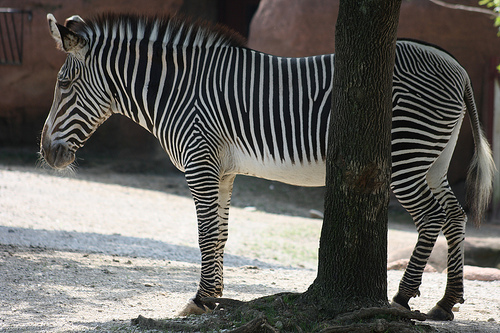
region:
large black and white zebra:
[36, 10, 491, 317]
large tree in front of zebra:
[301, 2, 413, 317]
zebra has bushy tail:
[457, 68, 498, 219]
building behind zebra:
[2, 4, 188, 150]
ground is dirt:
[2, 150, 497, 331]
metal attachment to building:
[0, 4, 26, 66]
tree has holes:
[342, 152, 384, 212]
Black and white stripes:
[186, 64, 303, 146]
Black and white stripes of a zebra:
[37, 52, 304, 184]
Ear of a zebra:
[34, 8, 84, 66]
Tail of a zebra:
[450, 64, 499, 224]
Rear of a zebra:
[408, 23, 493, 228]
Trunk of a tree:
[316, 11, 403, 241]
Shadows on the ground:
[16, 206, 150, 316]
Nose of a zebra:
[34, 133, 56, 165]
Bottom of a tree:
[281, 244, 382, 320]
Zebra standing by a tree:
[45, 11, 496, 326]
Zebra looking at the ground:
[30, 7, 495, 327]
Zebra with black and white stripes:
[35, 10, 492, 325]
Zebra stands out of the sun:
[35, 7, 491, 322]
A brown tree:
[316, 3, 396, 318]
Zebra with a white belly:
[35, 12, 495, 324]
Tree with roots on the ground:
[202, 20, 442, 331]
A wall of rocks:
[4, 3, 499, 191]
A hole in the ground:
[382, 226, 498, 292]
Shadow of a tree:
[0, 220, 287, 318]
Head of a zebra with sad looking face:
[35, 13, 137, 170]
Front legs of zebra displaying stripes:
[176, 134, 243, 314]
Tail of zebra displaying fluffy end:
[458, 71, 498, 220]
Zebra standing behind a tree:
[31, 15, 498, 316]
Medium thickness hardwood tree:
[318, 7, 395, 303]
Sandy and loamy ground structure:
[6, 183, 151, 320]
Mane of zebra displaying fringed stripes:
[88, 16, 243, 44]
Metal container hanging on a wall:
[0, 10, 33, 66]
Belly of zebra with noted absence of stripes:
[209, 123, 332, 185]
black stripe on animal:
[260, 52, 274, 182]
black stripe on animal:
[128, 35, 152, 115]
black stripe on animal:
[98, 38, 123, 89]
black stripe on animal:
[181, 151, 222, 175]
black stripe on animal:
[378, 103, 436, 135]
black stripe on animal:
[417, 75, 457, 115]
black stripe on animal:
[402, 185, 432, 209]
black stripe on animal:
[185, 169, 217, 191]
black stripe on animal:
[310, 56, 325, 161]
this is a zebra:
[25, 11, 488, 330]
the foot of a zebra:
[434, 185, 485, 317]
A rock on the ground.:
[96, 262, 111, 273]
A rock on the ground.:
[124, 276, 136, 288]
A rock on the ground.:
[133, 292, 145, 307]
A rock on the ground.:
[93, 305, 100, 316]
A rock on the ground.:
[121, 257, 128, 267]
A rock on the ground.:
[110, 257, 119, 266]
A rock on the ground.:
[241, 265, 267, 270]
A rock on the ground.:
[271, 279, 278, 286]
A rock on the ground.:
[267, 264, 272, 272]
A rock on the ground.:
[291, 287, 305, 296]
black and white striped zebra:
[22, 9, 480, 314]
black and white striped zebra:
[24, 8, 478, 309]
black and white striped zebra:
[30, 12, 481, 325]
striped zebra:
[28, 14, 478, 313]